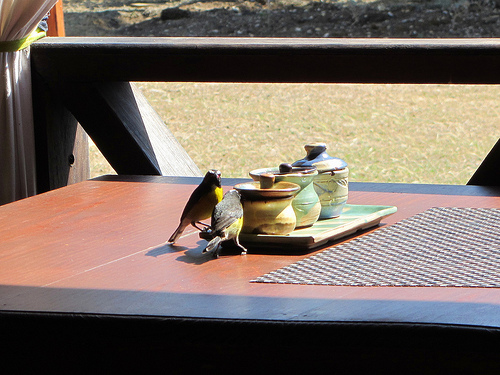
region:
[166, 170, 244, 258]
two yellow and grey birds on a table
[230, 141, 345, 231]
3 jars with lids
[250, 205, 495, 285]
woven place mat on a table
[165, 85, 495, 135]
dry grass in the yard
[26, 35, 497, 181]
wooden rail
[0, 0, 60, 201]
white pleated curtain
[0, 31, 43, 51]
green curtan tie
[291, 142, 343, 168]
blue ceramic lid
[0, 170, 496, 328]
brown table top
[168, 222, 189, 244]
grey feathered bird tail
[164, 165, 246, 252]
two small birds on a table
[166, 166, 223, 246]
a black and yellow bird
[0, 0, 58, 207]
a small curtain pulled back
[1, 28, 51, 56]
a green tie of a curtain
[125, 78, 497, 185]
brown and green grass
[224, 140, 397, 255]
three small pots on a plate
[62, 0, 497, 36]
the shadow of trees outside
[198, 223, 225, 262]
the tail feathers of a bird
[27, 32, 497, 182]
a wooden window frame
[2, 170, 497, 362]
a brown table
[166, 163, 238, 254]
a bird on a table.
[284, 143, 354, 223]
a jar on a plate.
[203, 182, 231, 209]
a bird with a yellow chest.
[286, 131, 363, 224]
a clay jar.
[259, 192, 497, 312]
a mat on a table.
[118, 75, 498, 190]
an open window.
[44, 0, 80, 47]
a light brown structure.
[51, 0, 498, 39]
the ground outside of a window.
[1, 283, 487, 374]
a dark brown section.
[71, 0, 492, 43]
grass on a hillside.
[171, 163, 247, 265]
two birds standing in sunlight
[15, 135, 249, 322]
two birds on a wooden table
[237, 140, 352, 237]
three little wooden containers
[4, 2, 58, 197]
edge of curtain with green tieback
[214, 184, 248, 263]
bird with yellow underbelly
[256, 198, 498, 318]
light and dark patterned placemat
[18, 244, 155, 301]
seam of wooden table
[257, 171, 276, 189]
knob on top of wooden container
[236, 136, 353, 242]
three little multi-colored pots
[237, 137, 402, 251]
three decorative containers on a tray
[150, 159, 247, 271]
two birds on a table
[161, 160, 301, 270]
two birds near pottery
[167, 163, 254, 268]
two birds with yellow bellies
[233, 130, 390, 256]
three crocks on a platter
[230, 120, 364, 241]
three crocks with lids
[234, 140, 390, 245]
three crocks with three lids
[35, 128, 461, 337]
A wooden table with birds on it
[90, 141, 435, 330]
A wooden table with crockery on it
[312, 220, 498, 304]
A placemant on a table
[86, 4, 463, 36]
Dirt in the background